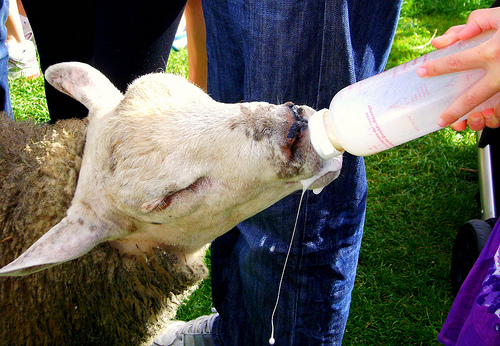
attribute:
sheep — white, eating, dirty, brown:
[23, 65, 323, 283]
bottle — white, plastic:
[311, 56, 471, 164]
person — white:
[417, 9, 498, 138]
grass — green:
[395, 5, 449, 94]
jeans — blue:
[198, 7, 377, 292]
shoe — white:
[157, 309, 218, 345]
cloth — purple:
[439, 228, 499, 333]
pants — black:
[31, 4, 182, 98]